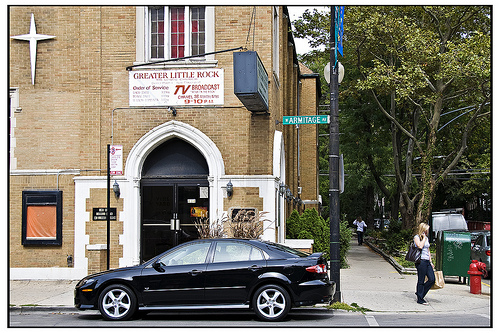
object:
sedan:
[72, 237, 340, 323]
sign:
[282, 114, 331, 125]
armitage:
[288, 116, 321, 123]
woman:
[412, 222, 436, 305]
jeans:
[414, 259, 437, 305]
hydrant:
[467, 259, 489, 295]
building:
[6, 3, 321, 278]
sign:
[128, 68, 226, 107]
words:
[173, 84, 182, 95]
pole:
[328, 5, 342, 306]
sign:
[338, 153, 345, 194]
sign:
[334, 5, 345, 58]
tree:
[472, 5, 494, 203]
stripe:
[364, 315, 380, 326]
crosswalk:
[364, 311, 491, 327]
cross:
[9, 12, 57, 86]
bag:
[404, 241, 422, 262]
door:
[137, 181, 176, 264]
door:
[176, 185, 211, 246]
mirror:
[151, 259, 166, 273]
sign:
[109, 144, 124, 176]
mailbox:
[440, 230, 473, 286]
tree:
[343, 51, 360, 197]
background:
[288, 7, 500, 260]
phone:
[422, 231, 426, 236]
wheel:
[96, 283, 141, 322]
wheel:
[252, 284, 293, 322]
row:
[420, 8, 441, 224]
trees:
[378, 7, 399, 231]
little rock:
[170, 70, 220, 79]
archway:
[135, 132, 212, 267]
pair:
[175, 219, 180, 230]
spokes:
[118, 292, 126, 301]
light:
[323, 61, 346, 85]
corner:
[450, 300, 493, 327]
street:
[342, 228, 490, 326]